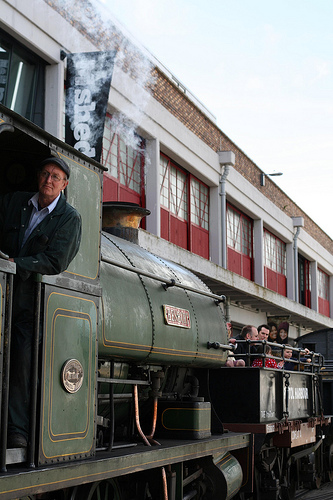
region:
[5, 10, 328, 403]
Train at the railway station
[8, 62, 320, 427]
Engine driver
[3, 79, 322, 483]
Green train engine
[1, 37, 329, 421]
Steam locomotive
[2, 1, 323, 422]
Coal fired train engine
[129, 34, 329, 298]
Red windows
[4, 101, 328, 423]
Tourists enjoying a train ride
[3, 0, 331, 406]
Train ride on a cloudy day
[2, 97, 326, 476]
A family enjoying a train ride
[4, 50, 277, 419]
Engineer driver in flat cap and cardigan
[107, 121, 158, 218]
the panels are red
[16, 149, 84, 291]
the person is a man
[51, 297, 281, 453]
the train is green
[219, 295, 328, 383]
the people are standing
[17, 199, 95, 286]
the jacket is black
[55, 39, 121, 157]
the text is white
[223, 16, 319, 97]
the sky is cloudy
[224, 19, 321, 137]
the clouds are white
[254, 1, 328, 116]
the sky is blue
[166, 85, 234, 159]
the bricks are brown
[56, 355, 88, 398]
gray metal attachment on train door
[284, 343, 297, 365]
small boy on back of train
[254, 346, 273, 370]
small girl with red top on back of train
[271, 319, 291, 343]
picture of two people on banner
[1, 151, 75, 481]
tour guide in front of train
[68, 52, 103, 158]
white wording on dark background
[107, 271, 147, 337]
green portion of the side of train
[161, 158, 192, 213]
window with red lines by train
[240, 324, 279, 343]
head and faces of two adult males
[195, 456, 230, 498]
large tire wheel on train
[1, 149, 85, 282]
train captain in his fifties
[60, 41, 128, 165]
black banner with "shed" written behind the smoke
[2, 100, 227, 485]
green train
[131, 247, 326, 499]
passengers on a green train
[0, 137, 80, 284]
train captain with black jacket looking out from the train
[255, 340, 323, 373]
two children from the passenger crowd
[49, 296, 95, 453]
gold-colored metallic plate on the side of the green train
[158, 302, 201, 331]
red plate on the side of a green train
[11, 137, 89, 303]
train captain wearing glasses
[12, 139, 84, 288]
train captain wearing a light blue collar shirt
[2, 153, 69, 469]
man in the front of the train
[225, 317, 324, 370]
people riding on the train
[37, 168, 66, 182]
glasses on man in front of train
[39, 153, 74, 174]
hat on man in front of train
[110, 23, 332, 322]
the building behind train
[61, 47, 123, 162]
black sign on side of building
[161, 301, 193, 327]
sign on side of train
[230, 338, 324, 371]
railing on car where people are riding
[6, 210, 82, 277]
left arm of man in front of train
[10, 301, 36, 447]
left leg of man in front of train